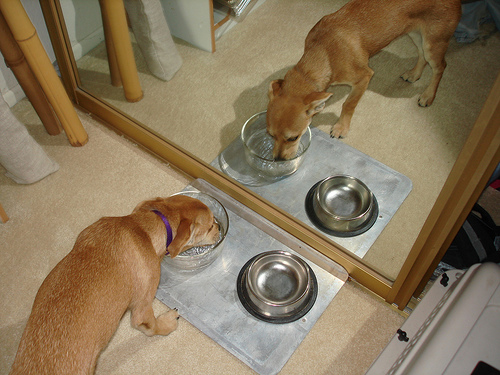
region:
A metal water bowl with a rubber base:
[224, 247, 328, 335]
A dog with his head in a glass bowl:
[149, 175, 234, 266]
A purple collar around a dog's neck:
[119, 187, 194, 255]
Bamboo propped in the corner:
[0, 40, 94, 156]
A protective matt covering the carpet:
[102, 170, 338, 359]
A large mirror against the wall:
[56, 1, 436, 288]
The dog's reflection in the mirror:
[250, 0, 450, 181]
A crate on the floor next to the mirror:
[379, 263, 489, 373]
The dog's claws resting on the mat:
[162, 303, 187, 320]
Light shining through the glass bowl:
[212, 139, 274, 190]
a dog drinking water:
[5, 180, 236, 373]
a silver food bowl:
[230, 235, 321, 335]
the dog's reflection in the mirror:
[180, 5, 477, 186]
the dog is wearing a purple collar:
[97, 170, 219, 275]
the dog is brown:
[7, 180, 232, 371]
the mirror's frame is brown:
[30, 0, 495, 330]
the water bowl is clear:
[151, 180, 245, 277]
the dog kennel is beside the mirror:
[333, 93, 498, 370]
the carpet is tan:
[2, 104, 386, 374]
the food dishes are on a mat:
[104, 167, 358, 373]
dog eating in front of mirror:
[3, 2, 493, 371]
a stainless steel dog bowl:
[229, 246, 321, 329]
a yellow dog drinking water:
[10, 187, 234, 374]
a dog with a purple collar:
[7, 194, 228, 372]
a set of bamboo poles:
[3, 2, 99, 155]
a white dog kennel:
[359, 245, 494, 372]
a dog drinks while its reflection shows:
[4, 1, 499, 373]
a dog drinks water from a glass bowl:
[4, 179, 231, 374]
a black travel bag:
[424, 190, 498, 270]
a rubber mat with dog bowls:
[116, 170, 358, 372]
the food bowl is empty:
[231, 246, 327, 321]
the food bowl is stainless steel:
[233, 249, 313, 324]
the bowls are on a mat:
[129, 184, 350, 366]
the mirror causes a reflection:
[175, 25, 447, 260]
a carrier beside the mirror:
[375, 267, 498, 372]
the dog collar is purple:
[145, 203, 178, 250]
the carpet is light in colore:
[0, 143, 161, 201]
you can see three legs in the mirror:
[330, 20, 466, 147]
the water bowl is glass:
[148, 185, 238, 268]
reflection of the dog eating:
[218, 51, 393, 176]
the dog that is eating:
[42, 216, 227, 373]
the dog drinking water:
[140, 180, 241, 287]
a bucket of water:
[149, 178, 238, 275]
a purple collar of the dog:
[128, 201, 179, 247]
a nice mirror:
[188, 30, 404, 207]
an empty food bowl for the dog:
[240, 245, 322, 350]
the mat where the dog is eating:
[162, 268, 304, 365]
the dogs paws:
[155, 309, 191, 346]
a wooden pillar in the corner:
[0, 23, 107, 160]